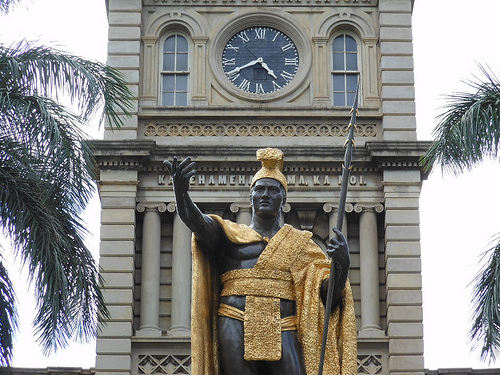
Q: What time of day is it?
A: Evening.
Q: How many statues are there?
A: One.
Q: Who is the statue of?
A: A man.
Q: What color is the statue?
A: Black.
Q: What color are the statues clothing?
A: Gold.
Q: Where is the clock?
A: A building.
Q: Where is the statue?
A: Near a large building.